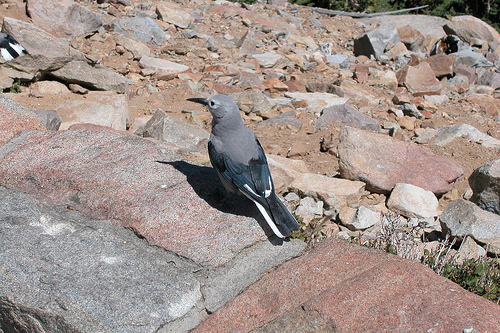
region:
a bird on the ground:
[25, 10, 471, 327]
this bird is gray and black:
[176, 75, 317, 245]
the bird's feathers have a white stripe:
[240, 172, 298, 242]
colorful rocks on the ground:
[10, 11, 455, 311]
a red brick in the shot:
[214, 253, 454, 331]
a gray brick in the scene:
[5, 202, 203, 332]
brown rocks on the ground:
[158, 10, 342, 77]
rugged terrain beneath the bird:
[52, 25, 479, 293]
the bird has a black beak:
[175, 88, 240, 121]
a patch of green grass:
[397, 219, 499, 313]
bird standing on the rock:
[188, 93, 303, 238]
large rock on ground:
[332, 124, 458, 199]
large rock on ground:
[0, 18, 125, 89]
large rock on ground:
[386, 182, 439, 216]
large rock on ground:
[288, 167, 365, 204]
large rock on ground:
[130, 108, 206, 152]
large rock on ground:
[357, 22, 399, 61]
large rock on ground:
[444, 12, 498, 67]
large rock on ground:
[405, 60, 437, 96]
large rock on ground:
[466, 156, 494, 212]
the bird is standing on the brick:
[186, 93, 298, 241]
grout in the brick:
[163, 235, 303, 332]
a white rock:
[389, 183, 437, 218]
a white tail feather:
[243, 190, 285, 239]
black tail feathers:
[256, 192, 298, 241]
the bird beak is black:
[186, 95, 205, 104]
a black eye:
[208, 100, 217, 108]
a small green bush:
[430, 243, 498, 289]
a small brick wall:
[0, 103, 497, 330]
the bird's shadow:
[158, 158, 250, 220]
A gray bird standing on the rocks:
[183, 86, 302, 240]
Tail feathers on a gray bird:
[251, 185, 301, 244]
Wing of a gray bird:
[206, 135, 271, 205]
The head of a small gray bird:
[186, 93, 248, 129]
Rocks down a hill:
[320, 16, 498, 248]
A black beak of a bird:
[184, 95, 208, 107]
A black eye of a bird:
[209, 99, 216, 106]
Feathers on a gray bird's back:
[223, 140, 265, 186]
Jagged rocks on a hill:
[7, 2, 487, 135]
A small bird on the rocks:
[186, 95, 301, 240]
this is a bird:
[174, 67, 311, 258]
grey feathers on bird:
[218, 122, 262, 168]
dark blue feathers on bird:
[228, 155, 273, 190]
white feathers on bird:
[253, 194, 282, 238]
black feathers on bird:
[268, 187, 301, 230]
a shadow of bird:
[153, 145, 238, 228]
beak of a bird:
[188, 82, 205, 112]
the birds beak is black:
[182, 85, 211, 114]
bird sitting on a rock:
[158, 70, 314, 275]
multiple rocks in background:
[133, 0, 460, 167]